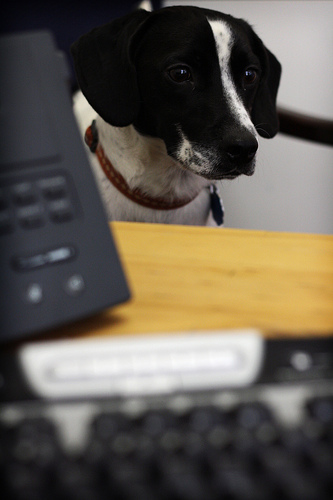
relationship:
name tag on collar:
[208, 182, 224, 221] [83, 118, 206, 212]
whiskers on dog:
[212, 176, 241, 189] [69, 0, 283, 225]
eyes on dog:
[163, 62, 258, 83] [69, 0, 283, 225]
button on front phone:
[65, 272, 83, 297] [5, 29, 130, 340]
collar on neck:
[83, 118, 206, 212] [88, 112, 207, 204]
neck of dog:
[88, 112, 207, 204] [69, 0, 283, 225]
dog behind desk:
[69, 0, 283, 225] [33, 221, 332, 341]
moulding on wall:
[274, 109, 328, 149] [165, 0, 330, 233]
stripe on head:
[208, 12, 256, 139] [77, 6, 280, 184]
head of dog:
[77, 6, 280, 184] [69, 0, 283, 225]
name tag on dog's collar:
[208, 182, 226, 226] [84, 118, 224, 222]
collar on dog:
[83, 118, 206, 212] [69, 0, 283, 225]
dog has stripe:
[69, 0, 283, 225] [205, 15, 263, 137]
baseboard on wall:
[272, 102, 332, 151] [261, 21, 328, 223]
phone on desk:
[3, 6, 136, 353] [4, 212, 326, 352]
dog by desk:
[58, 0, 288, 225] [81, 215, 331, 354]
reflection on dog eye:
[177, 66, 184, 74] [165, 63, 197, 85]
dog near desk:
[58, 0, 288, 225] [95, 215, 332, 338]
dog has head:
[69, 0, 283, 225] [61, 0, 287, 226]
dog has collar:
[69, 0, 283, 225] [79, 113, 214, 215]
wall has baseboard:
[274, 5, 329, 227] [275, 101, 331, 153]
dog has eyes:
[58, 0, 288, 225] [170, 59, 253, 86]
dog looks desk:
[58, 0, 288, 225] [95, 215, 332, 338]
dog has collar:
[58, 0, 288, 225] [83, 118, 206, 212]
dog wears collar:
[58, 0, 288, 225] [79, 121, 201, 210]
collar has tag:
[86, 124, 208, 220] [206, 177, 227, 227]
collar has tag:
[83, 118, 206, 212] [202, 177, 229, 229]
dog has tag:
[58, 0, 288, 225] [205, 176, 229, 226]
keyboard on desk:
[4, 322, 330, 496] [64, 212, 329, 341]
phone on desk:
[3, 6, 136, 353] [95, 215, 332, 338]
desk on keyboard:
[22, 221, 330, 356] [4, 322, 330, 496]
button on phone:
[43, 200, 70, 218] [7, 28, 122, 348]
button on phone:
[12, 169, 34, 207] [13, 65, 93, 315]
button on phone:
[14, 200, 51, 232] [9, 45, 104, 336]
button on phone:
[22, 249, 44, 274] [9, 43, 98, 326]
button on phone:
[65, 275, 82, 298] [6, 48, 87, 324]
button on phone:
[19, 279, 51, 305] [9, 43, 98, 326]